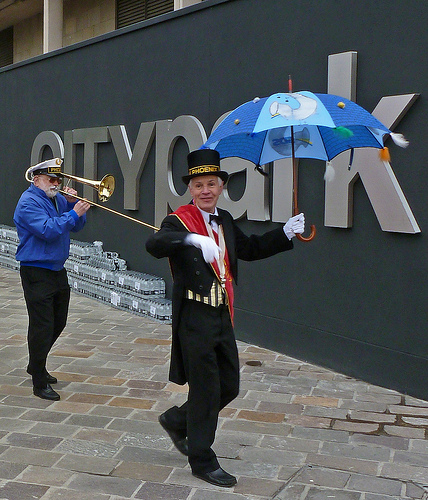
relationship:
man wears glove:
[144, 147, 305, 489] [281, 209, 305, 240]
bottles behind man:
[120, 268, 159, 295] [13, 157, 91, 401]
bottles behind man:
[133, 294, 178, 314] [13, 157, 91, 401]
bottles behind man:
[82, 247, 118, 270] [13, 157, 91, 401]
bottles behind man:
[0, 225, 18, 248] [13, 157, 91, 401]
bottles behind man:
[69, 270, 102, 303] [13, 157, 91, 401]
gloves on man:
[184, 234, 223, 263] [144, 147, 305, 489]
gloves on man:
[282, 212, 313, 235] [144, 147, 305, 489]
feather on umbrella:
[377, 145, 392, 162] [198, 72, 410, 241]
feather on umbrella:
[387, 131, 410, 147] [198, 72, 410, 241]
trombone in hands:
[51, 169, 160, 244] [56, 186, 91, 217]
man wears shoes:
[144, 147, 305, 489] [153, 398, 243, 490]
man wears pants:
[144, 147, 305, 489] [163, 305, 251, 469]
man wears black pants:
[13, 157, 91, 401] [16, 261, 72, 391]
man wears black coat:
[144, 147, 305, 489] [144, 198, 295, 386]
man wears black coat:
[144, 147, 305, 489] [146, 202, 294, 387]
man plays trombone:
[13, 157, 91, 401] [64, 170, 119, 202]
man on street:
[13, 157, 91, 401] [8, 386, 149, 489]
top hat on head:
[179, 149, 230, 188] [185, 177, 226, 210]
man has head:
[144, 147, 305, 489] [185, 177, 226, 210]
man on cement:
[120, 132, 261, 397] [69, 328, 196, 474]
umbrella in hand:
[214, 82, 387, 242] [184, 233, 219, 264]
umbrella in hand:
[214, 82, 387, 242] [278, 207, 309, 241]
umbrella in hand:
[214, 82, 387, 242] [61, 185, 78, 200]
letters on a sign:
[18, 49, 425, 247] [1, 4, 422, 404]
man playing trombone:
[13, 157, 91, 401] [51, 169, 160, 244]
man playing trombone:
[14, 143, 128, 406] [24, 161, 165, 231]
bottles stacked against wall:
[76, 252, 171, 337] [2, 21, 167, 319]